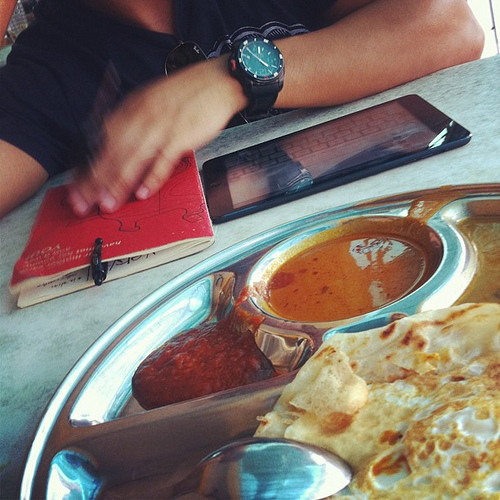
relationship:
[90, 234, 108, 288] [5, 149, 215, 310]
pen inside notebook